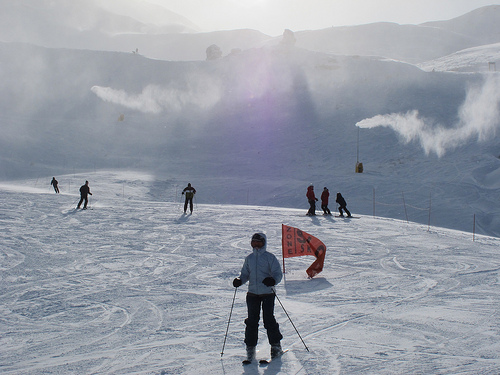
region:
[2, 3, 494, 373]
ski scene in a mountainous area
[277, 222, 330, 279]
red flag on a pole in the snow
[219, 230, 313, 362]
skier with light blue jacket and black pants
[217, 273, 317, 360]
black ski poles held by black gloved hands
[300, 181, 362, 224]
three skiers together on a slope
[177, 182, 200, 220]
skier dressed in black with white letters on chest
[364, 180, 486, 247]
four poles standing in the snow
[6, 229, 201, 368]
ski tracks on the snow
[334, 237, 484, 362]
ski tracks on the snow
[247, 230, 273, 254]
skier's head with black facemask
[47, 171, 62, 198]
a person skiing in the background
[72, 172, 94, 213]
a person skiing in the background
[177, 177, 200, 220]
a person skiing in the background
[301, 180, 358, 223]
a group of three skiiers in the background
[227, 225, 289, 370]
a person skiing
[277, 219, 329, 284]
a red flag planted in the snow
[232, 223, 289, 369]
a person wearing a winter jacket and snow pants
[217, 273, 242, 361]
a ski pole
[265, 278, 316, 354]
a ski pole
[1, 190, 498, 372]
snow on a hill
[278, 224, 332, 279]
A pink ski sign.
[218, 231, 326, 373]
A skier with a white jacket.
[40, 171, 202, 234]
Three people skiing down the ski slope.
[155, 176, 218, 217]
A skier skiing down the mountain.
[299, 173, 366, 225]
Three skiers talking on the mountain.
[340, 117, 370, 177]
A pole on the mountain.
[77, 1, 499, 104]
Mountain tops in the background.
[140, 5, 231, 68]
The sun shining on the mountains.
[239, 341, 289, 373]
Two skis on a skier.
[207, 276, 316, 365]
Two ski poles.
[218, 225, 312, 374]
skier wearing shite parka and black pants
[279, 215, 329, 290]
orange warning flag on ski slope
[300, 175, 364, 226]
three skiers on sunny day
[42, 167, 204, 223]
three skiers sking on ski slope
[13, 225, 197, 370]
snow with ski tracks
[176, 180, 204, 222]
one skier on sunny day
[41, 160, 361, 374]
group of skiers on ski slope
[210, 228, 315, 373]
person on skis with ski poles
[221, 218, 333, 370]
skier standing near orange flag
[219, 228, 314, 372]
skier with white jacket with hood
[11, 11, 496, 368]
a ski resort in the winter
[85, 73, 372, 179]
heaters are on the slopes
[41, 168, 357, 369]
people are skiing on a slope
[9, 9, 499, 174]
mountains are in the distance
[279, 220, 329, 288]
a directional flag is on the slope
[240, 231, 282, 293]
the skier has a gray down hoodie jacket on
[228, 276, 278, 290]
down ski gloves are on the skier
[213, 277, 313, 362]
the skier is holding ski poles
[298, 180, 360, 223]
three skiers are resting on the run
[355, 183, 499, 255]
a caution fence is on the ridge